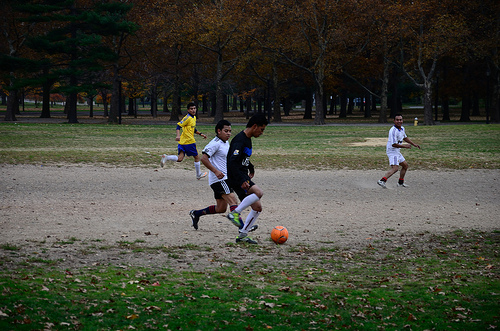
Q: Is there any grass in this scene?
A: Yes, there is grass.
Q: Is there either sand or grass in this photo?
A: Yes, there is grass.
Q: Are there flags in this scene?
A: No, there are no flags.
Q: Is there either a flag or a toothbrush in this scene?
A: No, there are no flags or toothbrushes.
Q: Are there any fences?
A: No, there are no fences.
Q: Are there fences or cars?
A: No, there are no fences or cars.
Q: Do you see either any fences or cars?
A: No, there are no fences or cars.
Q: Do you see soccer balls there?
A: Yes, there is a soccer ball.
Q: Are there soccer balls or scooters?
A: Yes, there is a soccer ball.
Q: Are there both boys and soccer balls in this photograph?
A: Yes, there are both a soccer ball and a boy.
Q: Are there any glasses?
A: No, there are no glasses.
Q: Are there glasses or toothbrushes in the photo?
A: No, there are no glasses or toothbrushes.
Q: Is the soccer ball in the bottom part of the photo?
A: Yes, the soccer ball is in the bottom of the image.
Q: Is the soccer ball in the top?
A: No, the soccer ball is in the bottom of the image.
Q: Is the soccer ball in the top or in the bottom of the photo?
A: The soccer ball is in the bottom of the image.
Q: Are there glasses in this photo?
A: No, there are no glasses.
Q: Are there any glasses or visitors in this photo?
A: No, there are no glasses or visitors.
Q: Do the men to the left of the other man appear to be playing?
A: Yes, the men are playing.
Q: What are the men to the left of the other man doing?
A: The men are playing.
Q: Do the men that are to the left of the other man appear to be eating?
A: No, the men are playing.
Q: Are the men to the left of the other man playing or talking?
A: The men are playing.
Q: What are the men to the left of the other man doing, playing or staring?
A: The men are playing.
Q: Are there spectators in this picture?
A: No, there are no spectators.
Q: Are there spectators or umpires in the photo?
A: No, there are no spectators or umpires.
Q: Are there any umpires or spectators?
A: No, there are no spectators or umpires.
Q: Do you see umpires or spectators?
A: No, there are no spectators or umpires.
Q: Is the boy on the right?
A: Yes, the boy is on the right of the image.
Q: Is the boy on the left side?
A: No, the boy is on the right of the image.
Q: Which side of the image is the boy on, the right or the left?
A: The boy is on the right of the image.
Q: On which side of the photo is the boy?
A: The boy is on the right of the image.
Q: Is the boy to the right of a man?
A: Yes, the boy is to the right of a man.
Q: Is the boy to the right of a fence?
A: No, the boy is to the right of a man.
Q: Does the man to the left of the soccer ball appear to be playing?
A: Yes, the man is playing.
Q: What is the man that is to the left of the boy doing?
A: The man is playing.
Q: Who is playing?
A: The man is playing.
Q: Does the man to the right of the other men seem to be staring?
A: No, the man is playing.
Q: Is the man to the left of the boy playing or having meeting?
A: The man is playing.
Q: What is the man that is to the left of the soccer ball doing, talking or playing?
A: The man is playing.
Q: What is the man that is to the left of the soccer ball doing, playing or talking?
A: The man is playing.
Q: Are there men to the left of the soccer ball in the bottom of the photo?
A: Yes, there is a man to the left of the soccer ball.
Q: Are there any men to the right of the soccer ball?
A: No, the man is to the left of the soccer ball.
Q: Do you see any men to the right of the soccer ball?
A: No, the man is to the left of the soccer ball.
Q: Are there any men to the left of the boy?
A: Yes, there is a man to the left of the boy.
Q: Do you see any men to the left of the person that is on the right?
A: Yes, there is a man to the left of the boy.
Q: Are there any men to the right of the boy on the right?
A: No, the man is to the left of the boy.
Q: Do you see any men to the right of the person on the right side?
A: No, the man is to the left of the boy.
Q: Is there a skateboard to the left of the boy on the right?
A: No, there is a man to the left of the boy.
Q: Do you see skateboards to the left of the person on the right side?
A: No, there is a man to the left of the boy.